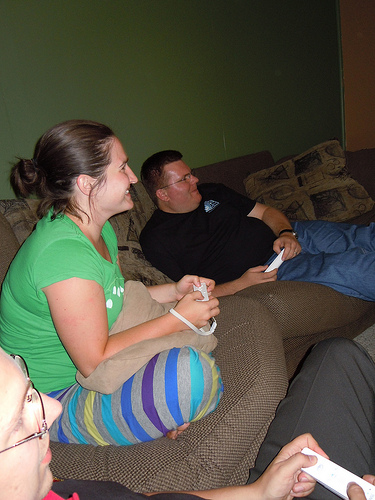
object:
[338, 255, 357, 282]
knee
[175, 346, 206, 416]
knee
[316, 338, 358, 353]
knee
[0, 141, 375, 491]
brown sofa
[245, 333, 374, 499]
trouser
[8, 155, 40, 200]
ponytail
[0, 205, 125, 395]
green shirt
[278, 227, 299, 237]
watch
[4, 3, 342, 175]
wall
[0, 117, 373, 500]
family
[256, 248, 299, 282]
controller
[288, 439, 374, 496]
controller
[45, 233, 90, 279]
driver's shoulder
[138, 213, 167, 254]
driver's shoulder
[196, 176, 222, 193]
driver's shoulder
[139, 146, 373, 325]
man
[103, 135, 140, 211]
person's face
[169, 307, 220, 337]
controller strap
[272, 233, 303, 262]
man's hands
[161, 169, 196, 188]
eyeglasses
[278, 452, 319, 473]
thumb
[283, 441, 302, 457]
part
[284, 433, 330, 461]
finger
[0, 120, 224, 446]
girl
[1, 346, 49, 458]
glasses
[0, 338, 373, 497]
man's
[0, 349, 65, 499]
face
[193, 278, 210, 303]
controller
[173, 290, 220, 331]
hand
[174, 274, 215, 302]
hand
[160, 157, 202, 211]
face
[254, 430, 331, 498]
hand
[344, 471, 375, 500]
hand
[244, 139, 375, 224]
big pillow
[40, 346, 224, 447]
pajama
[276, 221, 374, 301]
jeans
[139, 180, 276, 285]
black t-shirt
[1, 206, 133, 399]
shirt